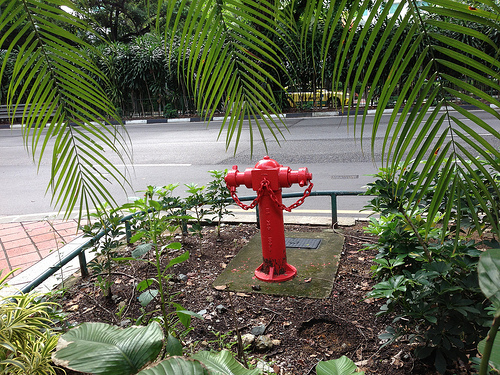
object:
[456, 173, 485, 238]
leaves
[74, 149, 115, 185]
stripe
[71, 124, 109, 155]
stripe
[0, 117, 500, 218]
road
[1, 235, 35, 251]
blocks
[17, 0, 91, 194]
branch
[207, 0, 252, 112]
branch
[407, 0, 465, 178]
branch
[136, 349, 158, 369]
lines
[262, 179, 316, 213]
chain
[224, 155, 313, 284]
hydrant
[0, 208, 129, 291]
sidewalk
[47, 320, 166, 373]
leaf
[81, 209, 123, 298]
plant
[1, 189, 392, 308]
rail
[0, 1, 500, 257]
plant area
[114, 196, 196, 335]
greenery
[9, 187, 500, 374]
enclosed area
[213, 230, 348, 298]
block